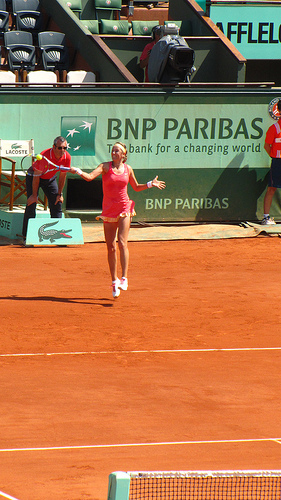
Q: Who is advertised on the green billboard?
A: BNP Paribas.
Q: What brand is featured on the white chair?
A: Lacoste.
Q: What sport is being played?
A: Tennis.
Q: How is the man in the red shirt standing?
A: Leaning forward.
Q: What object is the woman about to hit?
A: A tennis ball.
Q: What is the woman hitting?
A: Tennis ball.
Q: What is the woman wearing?
A: Tennis skirt.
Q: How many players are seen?
A: One.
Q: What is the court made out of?
A: Clay.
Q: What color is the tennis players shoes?
A: White.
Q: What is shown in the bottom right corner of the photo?
A: Net.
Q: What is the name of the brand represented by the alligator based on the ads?
A: Lacoste.